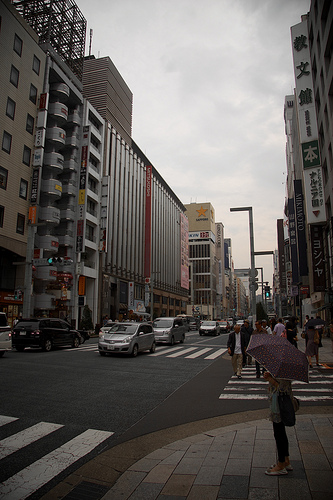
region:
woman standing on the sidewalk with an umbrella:
[244, 333, 301, 477]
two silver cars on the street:
[101, 311, 188, 358]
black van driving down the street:
[14, 315, 81, 353]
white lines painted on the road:
[2, 338, 332, 493]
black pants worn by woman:
[273, 419, 295, 462]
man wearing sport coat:
[225, 324, 252, 379]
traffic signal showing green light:
[263, 281, 272, 296]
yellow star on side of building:
[194, 204, 207, 219]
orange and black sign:
[73, 273, 88, 296]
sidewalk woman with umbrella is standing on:
[84, 408, 328, 499]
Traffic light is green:
[262, 284, 272, 300]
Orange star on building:
[193, 204, 207, 219]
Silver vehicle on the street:
[95, 321, 159, 357]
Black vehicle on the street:
[8, 314, 84, 353]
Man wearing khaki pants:
[228, 352, 246, 378]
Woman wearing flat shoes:
[262, 463, 294, 477]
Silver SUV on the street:
[151, 317, 186, 345]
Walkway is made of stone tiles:
[101, 412, 328, 498]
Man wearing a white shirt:
[232, 329, 243, 358]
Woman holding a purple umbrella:
[245, 331, 309, 475]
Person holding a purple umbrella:
[244, 333, 310, 476]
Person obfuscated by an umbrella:
[244, 331, 310, 477]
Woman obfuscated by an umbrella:
[244, 331, 310, 475]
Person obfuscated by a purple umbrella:
[244, 332, 311, 479]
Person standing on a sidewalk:
[240, 331, 309, 475]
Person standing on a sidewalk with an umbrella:
[244, 332, 310, 476]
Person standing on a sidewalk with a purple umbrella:
[244, 331, 311, 478]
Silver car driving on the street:
[97, 319, 154, 358]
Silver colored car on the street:
[98, 322, 156, 356]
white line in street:
[214, 385, 330, 404]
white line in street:
[222, 379, 330, 395]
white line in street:
[228, 375, 330, 389]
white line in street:
[205, 341, 229, 364]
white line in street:
[179, 338, 208, 364]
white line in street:
[143, 335, 181, 367]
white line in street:
[4, 410, 65, 460]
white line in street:
[0, 406, 17, 431]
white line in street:
[1, 416, 119, 498]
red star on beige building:
[193, 204, 212, 233]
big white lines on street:
[179, 347, 200, 360]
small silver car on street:
[107, 329, 134, 356]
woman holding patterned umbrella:
[244, 333, 305, 385]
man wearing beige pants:
[226, 344, 242, 373]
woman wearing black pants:
[265, 422, 297, 457]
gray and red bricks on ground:
[153, 456, 218, 486]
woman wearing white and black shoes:
[260, 466, 291, 482]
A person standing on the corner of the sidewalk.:
[246, 322, 309, 482]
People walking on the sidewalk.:
[205, 282, 332, 493]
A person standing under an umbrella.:
[237, 320, 313, 479]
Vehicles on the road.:
[12, 298, 255, 394]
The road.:
[1, 306, 327, 499]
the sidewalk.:
[36, 291, 331, 499]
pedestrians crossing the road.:
[222, 309, 331, 373]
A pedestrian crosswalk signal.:
[260, 281, 270, 299]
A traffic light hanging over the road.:
[41, 257, 68, 268]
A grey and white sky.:
[16, 2, 303, 294]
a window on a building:
[188, 244, 190, 256]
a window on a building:
[190, 243, 194, 249]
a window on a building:
[199, 231, 200, 237]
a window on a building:
[200, 231, 204, 234]